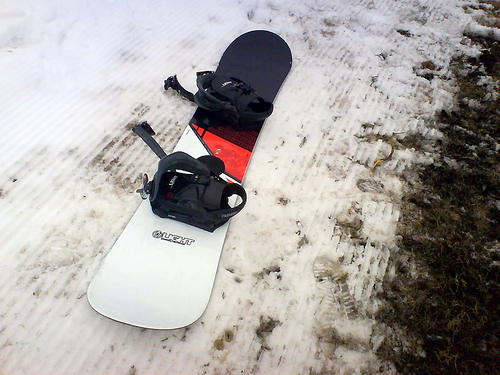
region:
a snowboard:
[78, 25, 315, 325]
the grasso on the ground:
[393, 291, 491, 373]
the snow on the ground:
[26, 48, 124, 150]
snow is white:
[16, 56, 103, 132]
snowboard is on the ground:
[78, 31, 300, 332]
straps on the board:
[130, 122, 170, 165]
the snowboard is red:
[211, 135, 250, 166]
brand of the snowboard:
[143, 225, 205, 250]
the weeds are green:
[425, 218, 496, 340]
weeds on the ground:
[401, 212, 490, 327]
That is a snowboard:
[88, 26, 315, 341]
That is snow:
[0, 0, 490, 374]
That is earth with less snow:
[387, 2, 497, 373]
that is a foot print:
[299, 250, 384, 363]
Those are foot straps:
[155, 69, 277, 241]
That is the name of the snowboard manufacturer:
[150, 226, 210, 256]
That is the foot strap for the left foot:
[130, 127, 261, 237]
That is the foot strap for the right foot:
[168, 71, 299, 125]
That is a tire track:
[82, 83, 187, 181]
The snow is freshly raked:
[0, 9, 464, 366]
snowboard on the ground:
[59, 29, 325, 347]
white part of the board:
[100, 234, 225, 325]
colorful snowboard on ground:
[90, 30, 328, 327]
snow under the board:
[253, 163, 341, 260]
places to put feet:
[118, 53, 289, 250]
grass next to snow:
[421, 234, 483, 308]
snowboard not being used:
[65, 27, 357, 320]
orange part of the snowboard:
[198, 133, 264, 180]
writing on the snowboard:
[148, 224, 210, 259]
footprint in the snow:
[294, 247, 365, 330]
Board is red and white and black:
[51, 7, 341, 346]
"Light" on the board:
[141, 222, 198, 254]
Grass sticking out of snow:
[293, 8, 498, 370]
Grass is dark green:
[357, 80, 494, 373]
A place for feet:
[153, 59, 280, 238]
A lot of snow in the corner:
[3, 3, 147, 104]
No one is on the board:
[57, 6, 307, 357]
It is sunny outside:
[11, 5, 496, 373]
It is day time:
[6, 6, 493, 373]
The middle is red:
[180, 114, 269, 185]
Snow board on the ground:
[167, 15, 294, 359]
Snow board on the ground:
[93, 72, 330, 277]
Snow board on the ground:
[128, 47, 227, 344]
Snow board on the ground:
[58, 182, 266, 358]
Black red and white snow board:
[106, 91, 306, 234]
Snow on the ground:
[314, 163, 448, 353]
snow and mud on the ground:
[365, 183, 473, 318]